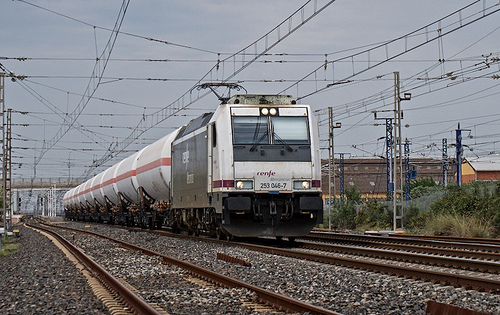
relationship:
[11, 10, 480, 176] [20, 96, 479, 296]
wires of a trainyard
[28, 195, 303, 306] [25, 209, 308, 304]
set of tracks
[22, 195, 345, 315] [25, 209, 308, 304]
set of tracks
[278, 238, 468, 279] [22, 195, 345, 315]
set of set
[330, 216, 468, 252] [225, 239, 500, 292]
set of set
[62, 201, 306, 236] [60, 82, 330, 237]
wheels under a train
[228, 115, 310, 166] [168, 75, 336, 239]
window of a car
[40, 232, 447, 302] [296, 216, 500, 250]
rocks between set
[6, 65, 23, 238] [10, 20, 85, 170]
poles between cables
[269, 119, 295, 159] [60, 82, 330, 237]
wipers on train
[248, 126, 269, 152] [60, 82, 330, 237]
wipers on train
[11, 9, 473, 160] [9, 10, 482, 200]
wires in sky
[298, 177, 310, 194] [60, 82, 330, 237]
headlight on train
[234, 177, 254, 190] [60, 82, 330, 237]
headlight on train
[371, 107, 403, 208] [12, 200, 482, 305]
pole in ground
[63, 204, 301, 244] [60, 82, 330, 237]
wheels on train